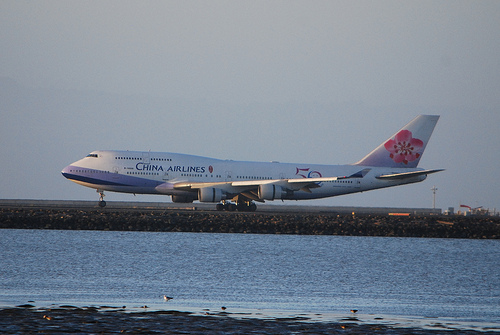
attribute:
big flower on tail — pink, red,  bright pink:
[373, 111, 433, 177]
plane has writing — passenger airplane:
[118, 151, 228, 189]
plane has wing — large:
[125, 103, 386, 312]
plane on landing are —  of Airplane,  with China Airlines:
[47, 105, 455, 269]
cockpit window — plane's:
[78, 134, 107, 170]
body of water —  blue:
[162, 240, 267, 290]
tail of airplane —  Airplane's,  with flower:
[336, 94, 460, 212]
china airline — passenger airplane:
[126, 139, 228, 216]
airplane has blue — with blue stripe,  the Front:
[57, 138, 157, 227]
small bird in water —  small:
[144, 265, 192, 333]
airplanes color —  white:
[58, 112, 450, 218]